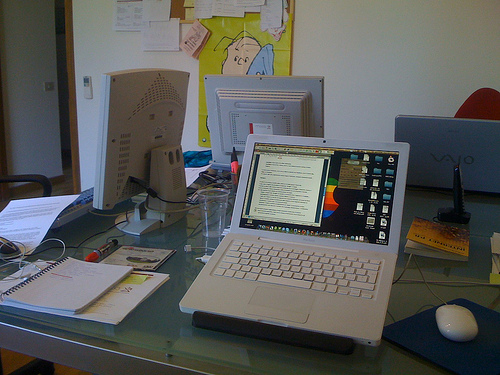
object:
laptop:
[178, 134, 410, 348]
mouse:
[435, 304, 478, 342]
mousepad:
[383, 297, 500, 374]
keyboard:
[214, 241, 381, 298]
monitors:
[93, 68, 191, 211]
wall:
[71, 0, 500, 192]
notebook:
[0, 256, 133, 315]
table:
[0, 165, 499, 374]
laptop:
[394, 114, 500, 193]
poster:
[198, 0, 294, 147]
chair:
[454, 87, 500, 121]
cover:
[403, 216, 470, 261]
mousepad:
[0, 256, 27, 279]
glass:
[197, 188, 231, 238]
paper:
[0, 194, 80, 262]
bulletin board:
[112, 0, 288, 59]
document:
[248, 153, 324, 223]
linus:
[220, 36, 275, 75]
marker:
[85, 239, 118, 261]